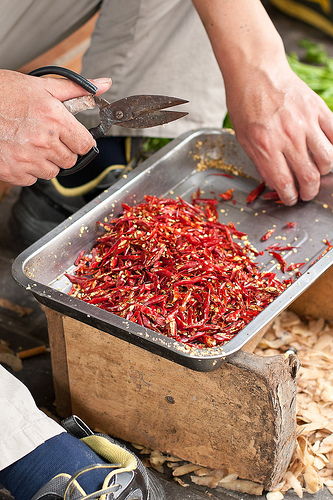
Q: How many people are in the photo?
A: One.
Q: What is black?
A: Scissor handles.